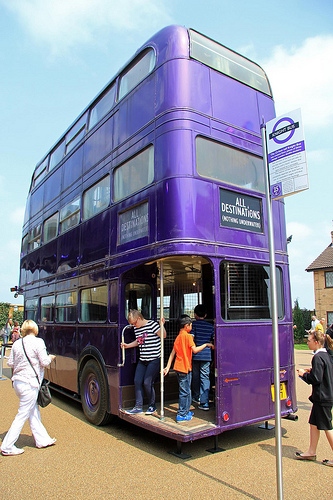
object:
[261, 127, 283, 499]
pole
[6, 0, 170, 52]
cloud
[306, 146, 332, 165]
cloud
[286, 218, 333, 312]
cloud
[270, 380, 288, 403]
license plate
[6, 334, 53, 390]
shirt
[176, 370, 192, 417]
pants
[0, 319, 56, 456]
lady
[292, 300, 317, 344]
bushes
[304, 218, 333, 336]
building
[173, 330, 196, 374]
shirt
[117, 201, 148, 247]
sign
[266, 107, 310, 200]
sign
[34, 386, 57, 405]
messenger bag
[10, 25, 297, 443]
bus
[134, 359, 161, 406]
pants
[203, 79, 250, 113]
ground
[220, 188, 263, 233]
all destinations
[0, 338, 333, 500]
road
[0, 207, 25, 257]
clouds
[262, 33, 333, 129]
clouds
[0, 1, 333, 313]
sky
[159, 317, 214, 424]
person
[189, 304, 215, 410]
person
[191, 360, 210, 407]
pants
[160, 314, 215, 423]
boy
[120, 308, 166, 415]
person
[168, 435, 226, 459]
bars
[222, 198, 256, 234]
letters